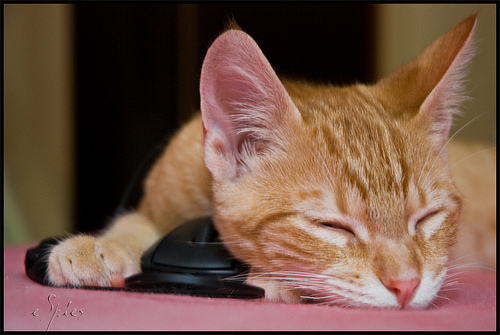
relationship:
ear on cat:
[198, 29, 303, 186] [266, 101, 455, 314]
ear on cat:
[373, 9, 480, 145] [266, 101, 455, 314]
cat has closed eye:
[47, 10, 497, 311] [316, 220, 358, 238]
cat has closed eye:
[47, 10, 497, 311] [413, 208, 442, 231]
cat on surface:
[47, 10, 497, 311] [5, 232, 498, 325]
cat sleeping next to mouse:
[47, 10, 497, 311] [137, 214, 249, 278]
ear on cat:
[198, 25, 304, 181] [47, 10, 497, 311]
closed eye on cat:
[282, 196, 370, 248] [47, 10, 497, 311]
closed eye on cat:
[404, 185, 454, 242] [47, 10, 497, 311]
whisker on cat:
[221, 269, 379, 308] [47, 10, 497, 311]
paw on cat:
[47, 235, 142, 288] [47, 10, 497, 311]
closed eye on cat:
[413, 208, 442, 231] [183, 44, 490, 331]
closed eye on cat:
[316, 220, 358, 238] [76, 17, 495, 330]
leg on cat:
[52, 178, 183, 295] [47, 10, 497, 311]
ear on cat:
[413, 12, 474, 138] [47, 10, 497, 311]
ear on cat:
[198, 29, 303, 186] [47, 10, 497, 311]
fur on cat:
[63, 89, 495, 264] [47, 10, 497, 311]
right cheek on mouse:
[212, 187, 286, 268] [150, 210, 256, 302]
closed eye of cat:
[413, 208, 442, 231] [47, 10, 497, 311]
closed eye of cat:
[316, 220, 358, 238] [47, 10, 497, 311]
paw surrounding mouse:
[41, 231, 145, 293] [127, 202, 267, 308]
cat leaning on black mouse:
[47, 10, 497, 311] [123, 214, 266, 299]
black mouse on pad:
[123, 214, 266, 299] [1, 240, 495, 329]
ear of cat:
[198, 25, 304, 181] [47, 10, 497, 311]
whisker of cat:
[221, 269, 379, 308] [136, 40, 499, 300]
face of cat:
[233, 101, 448, 280] [170, 35, 445, 298]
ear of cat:
[198, 29, 303, 186] [47, 10, 497, 311]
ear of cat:
[373, 9, 480, 145] [47, 10, 497, 311]